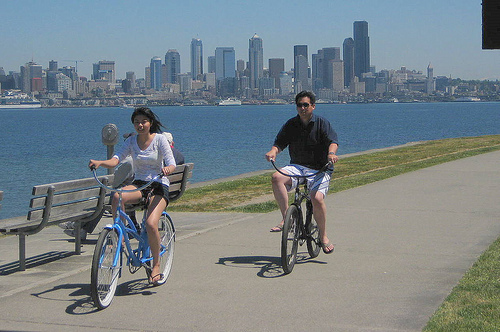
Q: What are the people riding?
A: Bikes.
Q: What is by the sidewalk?
A: River.